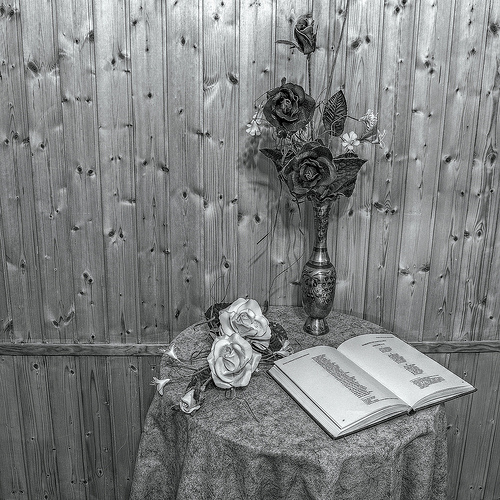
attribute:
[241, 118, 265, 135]
flower — white fabric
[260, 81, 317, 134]
rose — dark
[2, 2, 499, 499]
fence — wooden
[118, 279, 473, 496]
tablecloth — gray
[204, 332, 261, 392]
flower — white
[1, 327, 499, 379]
stripe — wooden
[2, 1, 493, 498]
photograph — black, white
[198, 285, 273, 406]
roses — silk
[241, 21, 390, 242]
roses — bouquet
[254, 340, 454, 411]
book — open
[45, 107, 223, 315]
fence — grey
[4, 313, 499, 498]
panel wall — wooden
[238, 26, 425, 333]
display — some type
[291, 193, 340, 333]
vase — decorated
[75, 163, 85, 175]
holes — tiny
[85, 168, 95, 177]
holes — tiny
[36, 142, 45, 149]
holes — tiny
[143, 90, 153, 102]
holes — tiny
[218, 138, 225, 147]
holes — tiny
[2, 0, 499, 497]
wall — wooden, shine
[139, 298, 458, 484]
table — small, round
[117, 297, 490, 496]
tablecloth — decorative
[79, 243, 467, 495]
table — round 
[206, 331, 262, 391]
flowers — artificial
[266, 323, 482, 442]
book — open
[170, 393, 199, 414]
petal — small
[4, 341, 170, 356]
line — wooden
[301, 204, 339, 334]
vase — decorative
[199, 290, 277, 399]
roses — white